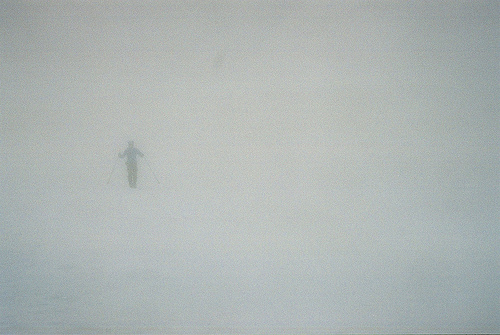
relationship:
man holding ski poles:
[118, 141, 147, 188] [107, 152, 156, 187]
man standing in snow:
[118, 141, 147, 188] [89, 180, 172, 222]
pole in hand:
[142, 157, 161, 186] [138, 145, 146, 158]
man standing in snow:
[118, 141, 147, 188] [102, 186, 170, 223]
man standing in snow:
[118, 141, 147, 188] [88, 182, 223, 214]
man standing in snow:
[118, 141, 147, 188] [92, 183, 178, 218]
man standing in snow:
[118, 141, 147, 188] [88, 182, 180, 223]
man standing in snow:
[118, 141, 147, 188] [99, 188, 159, 218]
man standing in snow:
[118, 141, 147, 188] [93, 177, 188, 240]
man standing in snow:
[118, 141, 147, 188] [83, 178, 236, 237]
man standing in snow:
[118, 141, 147, 188] [67, 183, 251, 266]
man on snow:
[118, 141, 147, 188] [75, 180, 187, 231]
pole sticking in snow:
[142, 157, 161, 186] [104, 185, 173, 251]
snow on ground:
[83, 188, 312, 291] [51, 99, 240, 261]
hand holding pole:
[108, 147, 132, 161] [107, 157, 121, 184]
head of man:
[121, 135, 140, 151] [114, 137, 148, 185]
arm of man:
[135, 149, 144, 166] [112, 138, 153, 187]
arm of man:
[114, 146, 127, 165] [108, 135, 153, 189]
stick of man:
[141, 158, 158, 188] [114, 133, 147, 194]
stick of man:
[104, 156, 121, 185] [114, 136, 144, 185]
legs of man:
[120, 160, 146, 187] [114, 140, 146, 189]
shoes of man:
[119, 180, 139, 193] [112, 135, 155, 193]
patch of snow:
[192, 146, 377, 280] [4, 5, 498, 333]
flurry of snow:
[209, 25, 397, 128] [4, 5, 498, 333]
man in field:
[118, 141, 147, 188] [116, 52, 254, 249]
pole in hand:
[107, 157, 121, 184] [112, 152, 152, 162]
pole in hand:
[97, 147, 126, 184] [108, 139, 148, 173]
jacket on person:
[119, 145, 148, 161] [113, 138, 156, 191]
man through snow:
[118, 141, 147, 188] [228, 246, 418, 306]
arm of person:
[135, 149, 144, 155] [116, 138, 159, 192]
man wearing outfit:
[118, 141, 147, 188] [116, 155, 142, 175]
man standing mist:
[118, 141, 147, 188] [245, 102, 372, 220]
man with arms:
[118, 141, 147, 188] [111, 139, 148, 163]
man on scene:
[118, 141, 147, 188] [23, 28, 460, 320]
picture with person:
[20, 60, 451, 324] [114, 130, 152, 186]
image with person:
[6, 14, 482, 324] [114, 127, 154, 201]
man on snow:
[118, 141, 147, 188] [304, 280, 418, 328]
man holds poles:
[121, 129, 148, 184] [85, 137, 174, 172]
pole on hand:
[137, 143, 167, 189] [136, 139, 146, 159]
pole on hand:
[107, 157, 121, 184] [107, 150, 124, 163]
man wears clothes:
[118, 141, 147, 188] [119, 145, 152, 194]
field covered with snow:
[205, 144, 308, 233] [153, 199, 269, 285]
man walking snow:
[118, 141, 147, 188] [190, 222, 260, 264]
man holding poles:
[118, 141, 147, 188] [97, 151, 141, 196]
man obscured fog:
[118, 141, 147, 188] [224, 141, 303, 221]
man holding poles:
[118, 141, 147, 188] [92, 153, 156, 163]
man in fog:
[118, 141, 147, 188] [195, 189, 272, 261]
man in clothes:
[118, 141, 147, 188] [124, 150, 167, 210]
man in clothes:
[118, 141, 147, 188] [108, 149, 164, 189]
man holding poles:
[118, 141, 147, 188] [109, 156, 153, 186]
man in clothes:
[118, 141, 147, 188] [116, 150, 157, 202]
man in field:
[118, 141, 147, 188] [4, 12, 484, 332]